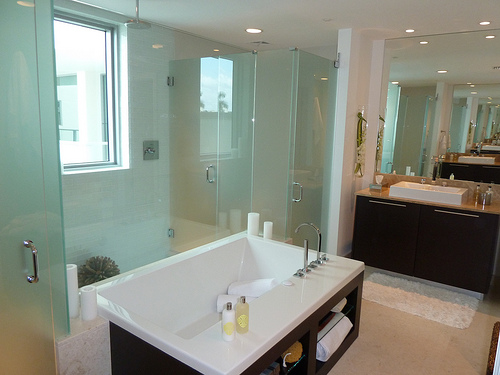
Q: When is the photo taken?
A: In the daytime.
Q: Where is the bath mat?
A: On the floor.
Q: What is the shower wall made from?
A: Glass.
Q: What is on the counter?
A: Toiletries.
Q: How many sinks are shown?
A: Two.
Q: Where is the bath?
A: Near the window.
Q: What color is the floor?
A: Off-white.